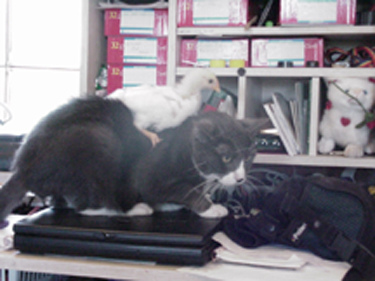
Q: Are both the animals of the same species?
A: No, they are cats and ducks.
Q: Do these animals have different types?
A: Yes, they are cats and ducks.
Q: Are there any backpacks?
A: Yes, there is a backpack.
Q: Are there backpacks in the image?
A: Yes, there is a backpack.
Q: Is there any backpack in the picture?
A: Yes, there is a backpack.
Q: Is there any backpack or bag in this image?
A: Yes, there is a backpack.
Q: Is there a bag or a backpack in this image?
A: Yes, there is a backpack.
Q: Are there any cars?
A: No, there are no cars.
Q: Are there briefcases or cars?
A: No, there are no cars or briefcases.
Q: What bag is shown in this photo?
A: The bag is a backpack.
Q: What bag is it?
A: The bag is a backpack.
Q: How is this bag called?
A: This is a backpack.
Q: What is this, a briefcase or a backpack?
A: This is a backpack.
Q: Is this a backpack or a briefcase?
A: This is a backpack.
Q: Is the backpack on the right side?
A: Yes, the backpack is on the right of the image.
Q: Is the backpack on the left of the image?
A: No, the backpack is on the right of the image.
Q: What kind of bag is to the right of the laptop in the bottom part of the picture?
A: The bag is a backpack.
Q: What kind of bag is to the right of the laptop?
A: The bag is a backpack.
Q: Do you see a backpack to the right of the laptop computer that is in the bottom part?
A: Yes, there is a backpack to the right of the laptop.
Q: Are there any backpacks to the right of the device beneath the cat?
A: Yes, there is a backpack to the right of the laptop.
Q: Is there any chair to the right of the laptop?
A: No, there is a backpack to the right of the laptop.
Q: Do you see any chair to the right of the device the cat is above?
A: No, there is a backpack to the right of the laptop.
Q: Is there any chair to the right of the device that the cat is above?
A: No, there is a backpack to the right of the laptop.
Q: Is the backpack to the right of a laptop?
A: Yes, the backpack is to the right of a laptop.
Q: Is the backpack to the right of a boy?
A: No, the backpack is to the right of a laptop.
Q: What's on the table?
A: The backpack is on the table.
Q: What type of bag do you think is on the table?
A: The bag is a backpack.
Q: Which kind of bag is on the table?
A: The bag is a backpack.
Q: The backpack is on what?
A: The backpack is on the table.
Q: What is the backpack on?
A: The backpack is on the table.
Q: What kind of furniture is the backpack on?
A: The backpack is on the table.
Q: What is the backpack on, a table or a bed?
A: The backpack is on a table.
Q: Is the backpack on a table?
A: Yes, the backpack is on a table.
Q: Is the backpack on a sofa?
A: No, the backpack is on a table.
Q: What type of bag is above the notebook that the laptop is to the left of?
A: The bag is a backpack.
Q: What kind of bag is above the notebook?
A: The bag is a backpack.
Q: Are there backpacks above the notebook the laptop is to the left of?
A: Yes, there is a backpack above the notebook.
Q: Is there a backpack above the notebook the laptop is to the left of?
A: Yes, there is a backpack above the notebook.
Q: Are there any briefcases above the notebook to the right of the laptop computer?
A: No, there is a backpack above the notebook.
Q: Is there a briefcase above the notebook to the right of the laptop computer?
A: No, there is a backpack above the notebook.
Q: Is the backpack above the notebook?
A: Yes, the backpack is above the notebook.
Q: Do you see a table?
A: Yes, there is a table.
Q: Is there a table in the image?
A: Yes, there is a table.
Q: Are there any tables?
A: Yes, there is a table.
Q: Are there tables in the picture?
A: Yes, there is a table.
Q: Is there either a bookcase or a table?
A: Yes, there is a table.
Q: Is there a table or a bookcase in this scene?
A: Yes, there is a table.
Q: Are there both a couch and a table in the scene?
A: No, there is a table but no couches.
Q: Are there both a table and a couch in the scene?
A: No, there is a table but no couches.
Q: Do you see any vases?
A: No, there are no vases.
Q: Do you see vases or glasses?
A: No, there are no vases or glasses.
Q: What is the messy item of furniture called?
A: The piece of furniture is a table.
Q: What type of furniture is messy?
A: The furniture is a table.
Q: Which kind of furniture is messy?
A: The furniture is a table.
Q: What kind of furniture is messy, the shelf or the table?
A: The table is messy.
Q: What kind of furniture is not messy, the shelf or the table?
A: The shelf is not messy.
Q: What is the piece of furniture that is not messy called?
A: The piece of furniture is a shelf.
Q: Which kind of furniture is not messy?
A: The furniture is a shelf.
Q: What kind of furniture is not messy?
A: The furniture is a shelf.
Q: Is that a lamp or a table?
A: That is a table.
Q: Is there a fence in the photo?
A: No, there are no fences.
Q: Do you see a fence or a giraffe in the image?
A: No, there are no fences or giraffes.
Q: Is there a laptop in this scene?
A: Yes, there is a laptop.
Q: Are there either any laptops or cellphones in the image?
A: Yes, there is a laptop.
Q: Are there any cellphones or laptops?
A: Yes, there is a laptop.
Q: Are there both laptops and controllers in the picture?
A: No, there is a laptop but no controllers.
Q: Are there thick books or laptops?
A: Yes, there is a thick laptop.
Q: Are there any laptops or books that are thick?
A: Yes, the laptop is thick.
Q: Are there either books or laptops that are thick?
A: Yes, the laptop is thick.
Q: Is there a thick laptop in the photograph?
A: Yes, there is a thick laptop.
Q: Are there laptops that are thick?
A: Yes, there is a laptop that is thick.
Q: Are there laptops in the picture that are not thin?
A: Yes, there is a thick laptop.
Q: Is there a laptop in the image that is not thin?
A: Yes, there is a thick laptop.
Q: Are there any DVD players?
A: No, there are no DVD players.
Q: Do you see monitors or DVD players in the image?
A: No, there are no DVD players or monitors.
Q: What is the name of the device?
A: The device is a laptop.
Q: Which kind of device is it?
A: The device is a laptop.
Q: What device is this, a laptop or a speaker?
A: This is a laptop.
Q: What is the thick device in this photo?
A: The device is a laptop.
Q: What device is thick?
A: The device is a laptop.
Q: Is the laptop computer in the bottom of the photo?
A: Yes, the laptop computer is in the bottom of the image.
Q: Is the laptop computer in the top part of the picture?
A: No, the laptop computer is in the bottom of the image.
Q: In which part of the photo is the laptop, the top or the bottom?
A: The laptop is in the bottom of the image.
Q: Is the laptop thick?
A: Yes, the laptop is thick.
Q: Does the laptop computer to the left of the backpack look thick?
A: Yes, the laptop computer is thick.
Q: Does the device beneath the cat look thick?
A: Yes, the laptop computer is thick.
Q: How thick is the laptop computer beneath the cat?
A: The laptop is thick.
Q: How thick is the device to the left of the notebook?
A: The laptop is thick.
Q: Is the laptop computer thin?
A: No, the laptop computer is thick.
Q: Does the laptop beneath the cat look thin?
A: No, the laptop is thick.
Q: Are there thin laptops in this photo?
A: No, there is a laptop but it is thick.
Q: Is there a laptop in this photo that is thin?
A: No, there is a laptop but it is thick.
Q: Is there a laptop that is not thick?
A: No, there is a laptop but it is thick.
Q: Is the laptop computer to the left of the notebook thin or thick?
A: The laptop is thick.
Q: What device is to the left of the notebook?
A: The device is a laptop.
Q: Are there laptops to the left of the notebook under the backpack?
A: Yes, there is a laptop to the left of the notebook.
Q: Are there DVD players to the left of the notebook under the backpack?
A: No, there is a laptop to the left of the notebook.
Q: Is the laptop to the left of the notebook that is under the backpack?
A: Yes, the laptop is to the left of the notebook.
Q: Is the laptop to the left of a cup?
A: No, the laptop is to the left of the notebook.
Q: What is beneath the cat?
A: The laptop is beneath the cat.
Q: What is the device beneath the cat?
A: The device is a laptop.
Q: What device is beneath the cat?
A: The device is a laptop.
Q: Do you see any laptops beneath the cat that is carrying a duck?
A: Yes, there is a laptop beneath the cat.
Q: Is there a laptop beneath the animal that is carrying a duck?
A: Yes, there is a laptop beneath the cat.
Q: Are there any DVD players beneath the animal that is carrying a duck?
A: No, there is a laptop beneath the cat.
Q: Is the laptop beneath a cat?
A: Yes, the laptop is beneath a cat.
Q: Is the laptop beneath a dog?
A: No, the laptop is beneath a cat.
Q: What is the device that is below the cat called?
A: The device is a laptop.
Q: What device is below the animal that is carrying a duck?
A: The device is a laptop.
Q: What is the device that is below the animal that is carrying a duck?
A: The device is a laptop.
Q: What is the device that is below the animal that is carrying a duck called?
A: The device is a laptop.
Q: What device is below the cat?
A: The device is a laptop.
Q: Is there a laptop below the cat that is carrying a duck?
A: Yes, there is a laptop below the cat.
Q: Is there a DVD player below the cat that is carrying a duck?
A: No, there is a laptop below the cat.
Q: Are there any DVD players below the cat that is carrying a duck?
A: No, there is a laptop below the cat.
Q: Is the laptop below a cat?
A: Yes, the laptop is below a cat.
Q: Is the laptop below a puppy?
A: No, the laptop is below a cat.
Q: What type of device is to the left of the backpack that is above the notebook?
A: The device is a laptop.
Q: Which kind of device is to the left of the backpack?
A: The device is a laptop.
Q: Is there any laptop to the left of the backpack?
A: Yes, there is a laptop to the left of the backpack.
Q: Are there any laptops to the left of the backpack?
A: Yes, there is a laptop to the left of the backpack.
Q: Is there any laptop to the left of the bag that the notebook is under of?
A: Yes, there is a laptop to the left of the backpack.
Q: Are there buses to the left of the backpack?
A: No, there is a laptop to the left of the backpack.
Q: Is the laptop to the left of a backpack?
A: Yes, the laptop is to the left of a backpack.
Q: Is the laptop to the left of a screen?
A: No, the laptop is to the left of a backpack.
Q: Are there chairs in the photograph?
A: No, there are no chairs.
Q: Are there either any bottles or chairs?
A: No, there are no chairs or bottles.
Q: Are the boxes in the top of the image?
A: Yes, the boxes are in the top of the image.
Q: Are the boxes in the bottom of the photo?
A: No, the boxes are in the top of the image.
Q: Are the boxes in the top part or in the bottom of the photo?
A: The boxes are in the top of the image.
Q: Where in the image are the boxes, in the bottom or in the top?
A: The boxes are in the top of the image.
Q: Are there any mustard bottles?
A: No, there are no mustard bottles.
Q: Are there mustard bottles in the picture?
A: No, there are no mustard bottles.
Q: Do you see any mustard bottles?
A: No, there are no mustard bottles.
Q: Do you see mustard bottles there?
A: No, there are no mustard bottles.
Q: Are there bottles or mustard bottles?
A: No, there are no mustard bottles or bottles.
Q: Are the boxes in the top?
A: Yes, the boxes are in the top of the image.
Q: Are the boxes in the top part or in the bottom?
A: The boxes are in the top of the image.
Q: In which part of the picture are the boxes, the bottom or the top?
A: The boxes are in the top of the image.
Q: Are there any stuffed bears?
A: Yes, there is a stuffed bear.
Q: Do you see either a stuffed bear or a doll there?
A: Yes, there is a stuffed bear.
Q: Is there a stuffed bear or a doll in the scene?
A: Yes, there is a stuffed bear.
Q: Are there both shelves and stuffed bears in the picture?
A: Yes, there are both a stuffed bear and a shelf.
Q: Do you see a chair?
A: No, there are no chairs.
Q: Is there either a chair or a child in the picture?
A: No, there are no chairs or children.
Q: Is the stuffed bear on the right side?
A: Yes, the stuffed bear is on the right of the image.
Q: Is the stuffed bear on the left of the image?
A: No, the stuffed bear is on the right of the image.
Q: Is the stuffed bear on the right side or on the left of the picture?
A: The stuffed bear is on the right of the image.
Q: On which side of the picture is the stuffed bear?
A: The stuffed bear is on the right of the image.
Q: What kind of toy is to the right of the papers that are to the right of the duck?
A: The toy is a stuffed bear.